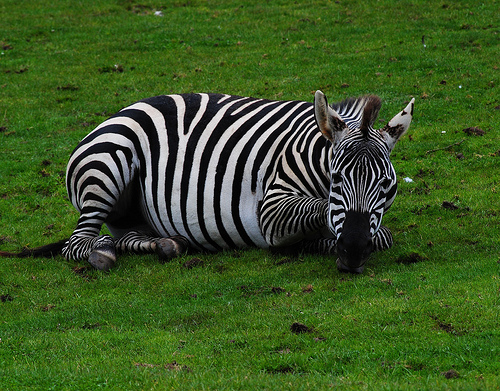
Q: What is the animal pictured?
A: Zebra.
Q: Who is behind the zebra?
A: Nobody.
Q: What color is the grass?
A: Green.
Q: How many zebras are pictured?
A: 1.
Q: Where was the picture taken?
A: Field.